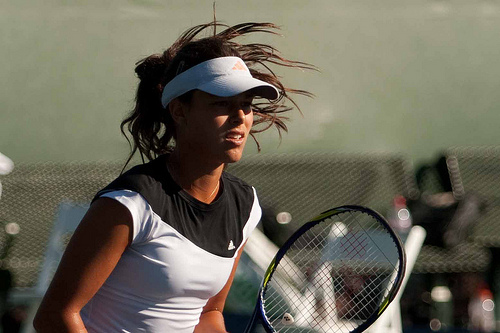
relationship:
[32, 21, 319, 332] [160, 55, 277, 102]
girl has cap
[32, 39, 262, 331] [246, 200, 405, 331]
girl has racket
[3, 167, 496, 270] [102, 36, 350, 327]
fence behind girl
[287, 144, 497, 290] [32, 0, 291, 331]
people behind girl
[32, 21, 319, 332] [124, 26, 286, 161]
girl long hair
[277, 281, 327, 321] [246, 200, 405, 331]
dampener on racket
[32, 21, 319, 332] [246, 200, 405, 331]
girl holding racket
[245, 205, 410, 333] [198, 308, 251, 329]
racket in woman's hand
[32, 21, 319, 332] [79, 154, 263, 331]
girl wearing shirt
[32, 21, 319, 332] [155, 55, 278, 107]
girl wearing cap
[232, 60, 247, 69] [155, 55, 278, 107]
orange symbol on cap